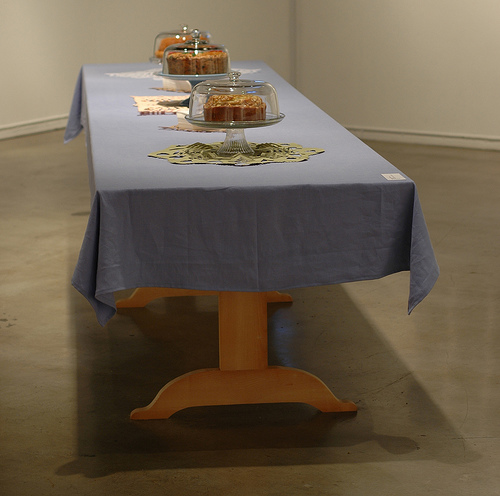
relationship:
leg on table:
[130, 290, 360, 422] [82, 61, 414, 420]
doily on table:
[148, 139, 323, 168] [82, 61, 414, 420]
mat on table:
[160, 114, 239, 134] [82, 61, 414, 420]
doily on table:
[105, 65, 261, 83] [82, 61, 414, 420]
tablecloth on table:
[60, 58, 439, 330] [82, 61, 414, 420]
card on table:
[381, 171, 405, 183] [82, 61, 414, 420]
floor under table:
[3, 124, 499, 496] [82, 61, 414, 420]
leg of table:
[130, 290, 360, 422] [82, 61, 414, 420]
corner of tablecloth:
[69, 189, 137, 327] [60, 58, 439, 330]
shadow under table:
[55, 228, 477, 478] [82, 61, 414, 420]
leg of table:
[116, 281, 294, 310] [82, 61, 414, 420]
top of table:
[83, 59, 410, 191] [82, 61, 414, 420]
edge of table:
[92, 178, 414, 201] [82, 61, 414, 420]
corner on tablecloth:
[407, 185, 439, 317] [60, 58, 439, 330]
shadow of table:
[55, 228, 477, 478] [82, 61, 414, 420]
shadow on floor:
[55, 228, 477, 478] [3, 124, 499, 496]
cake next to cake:
[204, 93, 266, 120] [168, 50, 228, 76]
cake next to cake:
[168, 50, 228, 76] [157, 34, 206, 58]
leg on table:
[116, 281, 294, 310] [82, 61, 414, 420]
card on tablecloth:
[381, 171, 405, 183] [60, 58, 439, 330]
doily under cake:
[148, 139, 323, 168] [204, 93, 266, 120]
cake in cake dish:
[204, 93, 266, 120] [185, 69, 286, 157]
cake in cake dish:
[168, 50, 228, 76] [153, 29, 241, 107]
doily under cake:
[105, 65, 261, 83] [157, 34, 206, 58]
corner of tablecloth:
[407, 185, 439, 317] [60, 58, 439, 330]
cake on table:
[204, 93, 266, 120] [82, 61, 414, 420]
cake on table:
[168, 50, 228, 76] [82, 61, 414, 420]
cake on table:
[157, 34, 206, 58] [82, 61, 414, 420]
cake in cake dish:
[157, 34, 206, 58] [150, 23, 215, 62]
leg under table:
[130, 290, 360, 422] [82, 61, 414, 420]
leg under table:
[116, 281, 294, 310] [82, 61, 414, 420]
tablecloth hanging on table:
[60, 58, 439, 330] [82, 61, 414, 420]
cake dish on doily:
[185, 69, 286, 157] [148, 139, 323, 168]